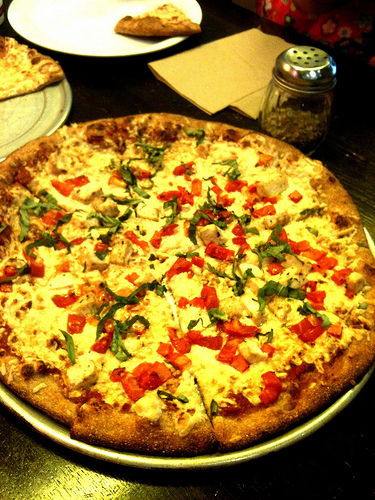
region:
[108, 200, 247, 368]
a whole pizza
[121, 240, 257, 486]
a whole pizza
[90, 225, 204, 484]
a whole pizza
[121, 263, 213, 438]
a whole pizza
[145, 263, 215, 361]
a whole pizza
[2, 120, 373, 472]
a large pizza on a silver tray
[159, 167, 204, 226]
green and red toppings on the pizza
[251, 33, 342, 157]
a shaker of oregano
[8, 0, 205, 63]
a white plate with a bite of pizza on it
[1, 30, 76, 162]
a silver pan with a single slice of pizza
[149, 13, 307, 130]
a brown paper napkin on the table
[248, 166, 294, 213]
the pizza is topped with chicken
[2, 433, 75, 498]
a brown wooden table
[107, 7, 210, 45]
a brown pizza crust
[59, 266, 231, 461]
the pizza is cut in triangles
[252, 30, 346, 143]
A jar of pizza seasoning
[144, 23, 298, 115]
A couple of brown napkins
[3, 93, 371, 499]
A pizza with many toppings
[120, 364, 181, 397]
Red tomatoes topping a pizza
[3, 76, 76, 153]
A gray metal pizza pan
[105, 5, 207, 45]
A slice of pizza on a white plate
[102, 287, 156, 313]
Green pizza toppings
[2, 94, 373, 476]
A pizza on a gray metal pizza pan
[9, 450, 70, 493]
A black wooden table surface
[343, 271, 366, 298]
Chicken topping a pizza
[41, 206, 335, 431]
the pizza is large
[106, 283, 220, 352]
the toppings are red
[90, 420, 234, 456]
the crust is brown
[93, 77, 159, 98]
the table is wooden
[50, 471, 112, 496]
light reflection is on the table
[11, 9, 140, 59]
the plate is white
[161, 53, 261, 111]
the paper is brown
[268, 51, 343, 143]
salt shaker is made of glass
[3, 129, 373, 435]
the pizza is cut in to triangular pieces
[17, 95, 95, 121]
the plate is mettalic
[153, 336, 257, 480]
a whole pizza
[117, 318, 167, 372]
a whole pizza